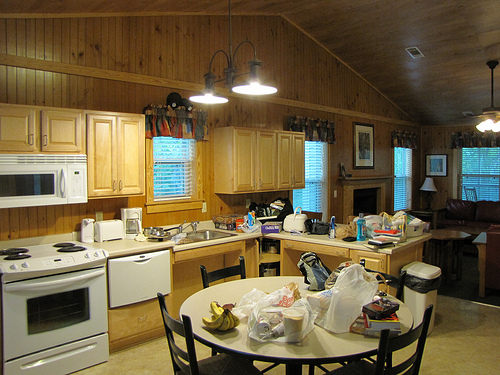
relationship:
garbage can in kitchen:
[403, 262, 441, 329] [1, 0, 499, 373]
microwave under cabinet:
[3, 164, 87, 210] [3, 105, 86, 154]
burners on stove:
[1, 243, 86, 261] [1, 233, 111, 372]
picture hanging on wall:
[352, 123, 375, 170] [331, 119, 453, 224]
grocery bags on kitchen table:
[245, 266, 379, 344] [181, 276, 414, 374]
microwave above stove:
[3, 164, 87, 210] [1, 233, 111, 372]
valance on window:
[149, 106, 206, 138] [146, 108, 204, 209]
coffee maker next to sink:
[121, 206, 145, 243] [178, 229, 237, 245]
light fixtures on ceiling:
[189, 2, 278, 107] [3, 0, 496, 126]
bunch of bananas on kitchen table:
[202, 301, 240, 331] [181, 276, 414, 374]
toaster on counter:
[95, 218, 126, 244] [93, 237, 170, 257]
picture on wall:
[352, 123, 375, 170] [331, 119, 453, 224]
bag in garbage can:
[404, 276, 440, 294] [403, 262, 441, 329]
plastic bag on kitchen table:
[245, 283, 316, 343] [181, 276, 414, 374]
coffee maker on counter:
[121, 206, 145, 243] [93, 237, 170, 257]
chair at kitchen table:
[158, 294, 258, 372] [181, 276, 414, 374]